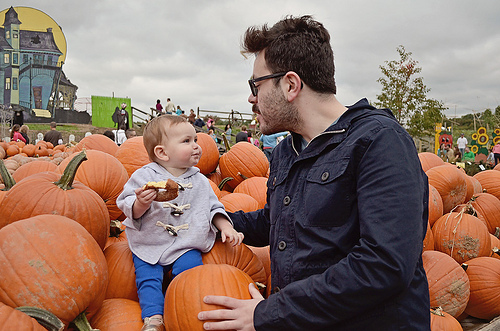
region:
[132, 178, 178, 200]
A donut in the infant's hand.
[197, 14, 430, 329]
A man with a young beard.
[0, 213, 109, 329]
A pumpkin in a pile of pumpkins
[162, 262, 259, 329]
A pumpkin in a pile of pumpkins.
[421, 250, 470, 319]
A pumpkin in a pile of pumpkins.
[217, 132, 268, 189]
A pumpkin in a pile of pumpkins.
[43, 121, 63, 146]
A person in the background.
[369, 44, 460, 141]
A tree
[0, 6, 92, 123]
A cutout decoration.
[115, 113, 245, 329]
An infant holding a donut.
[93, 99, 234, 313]
baby sitting on pumpkins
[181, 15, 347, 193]
man looking at baby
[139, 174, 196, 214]
donut in baby's hand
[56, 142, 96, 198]
stems on top of pumpkin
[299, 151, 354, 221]
pocket on man's jacket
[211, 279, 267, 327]
hand on side of pumpkin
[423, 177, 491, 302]
pile of dirty pumpkins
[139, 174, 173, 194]
bites taken out of donut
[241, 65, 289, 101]
black glasses on man's face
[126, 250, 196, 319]
blue pants on legs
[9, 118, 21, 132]
the head of a person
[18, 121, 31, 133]
the head of a person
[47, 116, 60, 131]
the head of a person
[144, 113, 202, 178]
the head of a person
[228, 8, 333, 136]
the head of a person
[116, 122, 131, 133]
the head of a person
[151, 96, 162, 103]
the head of a person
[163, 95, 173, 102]
the head of a person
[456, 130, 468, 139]
the head of a person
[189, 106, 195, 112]
the head of a person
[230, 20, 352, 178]
A man with short hair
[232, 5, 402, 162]
A man with brown hair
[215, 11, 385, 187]
A man with glasses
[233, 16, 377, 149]
A man with black glasses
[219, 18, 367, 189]
A man with a beard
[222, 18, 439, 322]
A man wearing a jacket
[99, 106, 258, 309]
A young child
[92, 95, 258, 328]
A young child holding a donut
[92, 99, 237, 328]
A young child wearing a jacket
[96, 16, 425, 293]
A man looking at a child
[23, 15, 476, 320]
people amongst some pumpkins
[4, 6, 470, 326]
people out amongst some pumpkins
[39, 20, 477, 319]
people amongst several pumpkins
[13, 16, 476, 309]
people amongst lots of pumpkins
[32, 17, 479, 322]
people amongst many pumpkins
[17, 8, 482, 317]
people with many pumpkins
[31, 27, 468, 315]
people with several pumpkins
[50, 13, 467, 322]
people with lots of pumpkins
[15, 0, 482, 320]
people having fun with many pumpkins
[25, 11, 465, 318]
people sharing moment with many pumpkins